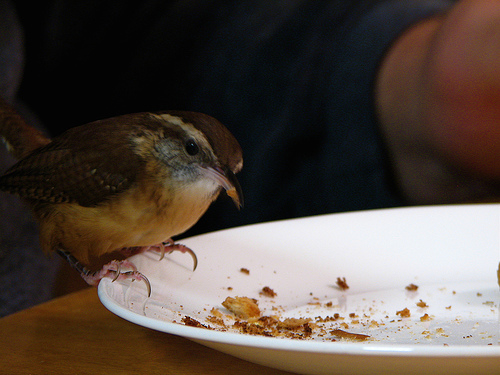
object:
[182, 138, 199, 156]
eye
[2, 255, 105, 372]
tabletop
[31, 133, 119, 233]
feathers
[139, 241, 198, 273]
feet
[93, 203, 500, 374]
plate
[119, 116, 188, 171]
feathers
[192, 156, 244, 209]
beak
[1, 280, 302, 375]
table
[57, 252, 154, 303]
bird's feet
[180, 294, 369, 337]
food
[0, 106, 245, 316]
bird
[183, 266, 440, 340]
crumbs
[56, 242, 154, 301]
leg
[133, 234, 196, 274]
leg